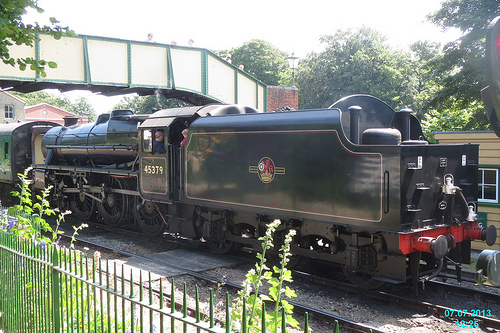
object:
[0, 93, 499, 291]
train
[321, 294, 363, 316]
pebbles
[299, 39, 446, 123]
trees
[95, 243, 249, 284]
walk way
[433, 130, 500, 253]
building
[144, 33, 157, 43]
people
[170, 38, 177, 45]
people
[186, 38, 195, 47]
people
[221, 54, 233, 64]
people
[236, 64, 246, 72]
people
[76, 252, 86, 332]
rod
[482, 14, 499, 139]
light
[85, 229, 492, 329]
tracks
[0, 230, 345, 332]
fence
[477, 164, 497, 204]
window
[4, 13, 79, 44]
tree limb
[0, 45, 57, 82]
tree limb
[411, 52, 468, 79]
tree limb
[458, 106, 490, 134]
tree limb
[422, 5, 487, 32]
tree limb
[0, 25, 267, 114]
bridge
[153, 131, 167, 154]
driver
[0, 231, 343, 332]
gate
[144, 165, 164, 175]
45379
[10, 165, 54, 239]
green leafy